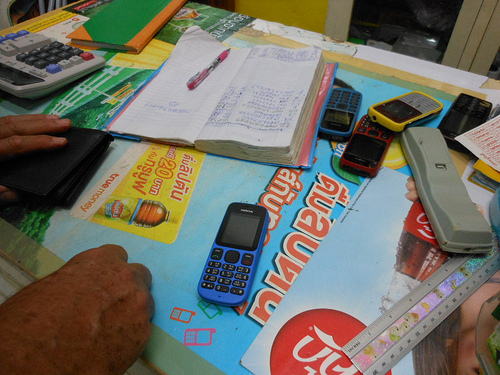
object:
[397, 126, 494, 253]
remote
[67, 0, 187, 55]
book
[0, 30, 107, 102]
calculator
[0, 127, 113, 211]
wallet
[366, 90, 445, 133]
yellow cellphone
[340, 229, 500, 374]
ruler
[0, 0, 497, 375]
table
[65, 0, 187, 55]
notebook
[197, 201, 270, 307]
cell phone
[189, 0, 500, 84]
ground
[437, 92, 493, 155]
cellphones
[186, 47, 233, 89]
pen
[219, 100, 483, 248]
many windows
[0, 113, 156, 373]
person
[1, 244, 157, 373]
hand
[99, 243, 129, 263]
finger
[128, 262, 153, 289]
finger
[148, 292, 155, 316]
finger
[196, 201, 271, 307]
phone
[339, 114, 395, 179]
phone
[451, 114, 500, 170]
paper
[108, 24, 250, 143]
paper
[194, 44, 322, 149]
paper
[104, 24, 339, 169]
book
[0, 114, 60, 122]
finger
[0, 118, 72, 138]
finger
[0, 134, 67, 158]
finger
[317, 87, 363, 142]
cell phone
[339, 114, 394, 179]
cell phone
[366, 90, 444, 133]
cell phone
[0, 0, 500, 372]
desk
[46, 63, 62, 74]
button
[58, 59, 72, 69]
button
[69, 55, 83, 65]
button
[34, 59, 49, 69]
button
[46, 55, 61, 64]
button